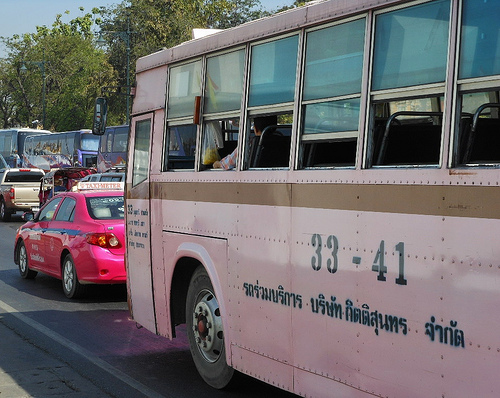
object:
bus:
[121, 0, 499, 398]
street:
[0, 212, 307, 398]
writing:
[241, 232, 466, 353]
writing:
[127, 202, 150, 251]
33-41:
[309, 232, 409, 287]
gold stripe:
[125, 181, 500, 220]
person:
[217, 113, 277, 172]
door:
[124, 109, 159, 336]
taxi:
[12, 178, 128, 301]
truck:
[0, 166, 46, 223]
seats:
[461, 101, 500, 164]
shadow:
[1, 344, 287, 398]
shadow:
[0, 265, 128, 305]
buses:
[21, 128, 101, 170]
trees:
[0, 10, 113, 129]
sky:
[0, 0, 314, 66]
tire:
[184, 264, 239, 391]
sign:
[70, 180, 124, 192]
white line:
[0, 298, 165, 398]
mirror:
[92, 97, 108, 135]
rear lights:
[105, 232, 122, 250]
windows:
[443, 0, 500, 168]